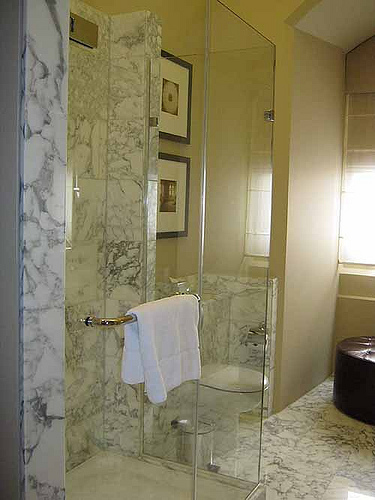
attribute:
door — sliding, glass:
[192, 0, 276, 497]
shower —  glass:
[58, 1, 278, 497]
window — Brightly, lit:
[336, 75, 372, 265]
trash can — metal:
[173, 417, 220, 471]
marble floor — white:
[161, 372, 373, 497]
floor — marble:
[232, 376, 371, 499]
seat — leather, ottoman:
[331, 324, 373, 416]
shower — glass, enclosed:
[80, 196, 276, 429]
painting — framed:
[160, 44, 192, 143]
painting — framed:
[155, 151, 191, 239]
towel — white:
[120, 293, 200, 404]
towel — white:
[115, 270, 221, 413]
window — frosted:
[338, 153, 374, 263]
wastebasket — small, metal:
[135, 410, 226, 451]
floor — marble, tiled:
[150, 372, 371, 497]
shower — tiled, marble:
[64, 2, 295, 494]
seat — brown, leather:
[336, 332, 374, 425]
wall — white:
[146, 82, 209, 107]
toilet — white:
[192, 357, 268, 466]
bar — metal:
[79, 291, 214, 328]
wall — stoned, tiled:
[1, 0, 164, 497]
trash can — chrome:
[166, 412, 220, 478]